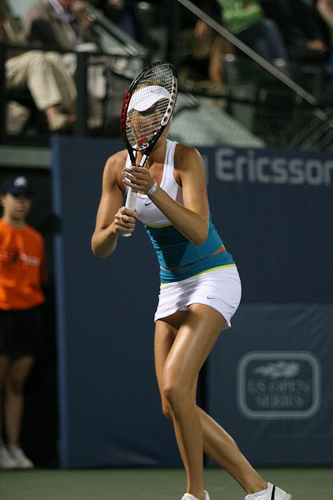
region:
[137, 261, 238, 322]
woman's skirt is white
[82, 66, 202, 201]
woman holding tennis racket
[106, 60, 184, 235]
racket is red and black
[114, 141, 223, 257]
shirt is blue and white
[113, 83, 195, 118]
woman wearing a visor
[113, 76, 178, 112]
the visor is white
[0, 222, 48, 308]
person's shirt is red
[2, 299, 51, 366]
person's shorts are black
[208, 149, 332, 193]
white letters on wall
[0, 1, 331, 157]
people sitting in stands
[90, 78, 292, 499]
woman is playing tennis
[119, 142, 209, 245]
woman's tan left arm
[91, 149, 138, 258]
woman's tan right arm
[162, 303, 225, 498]
woman's tan left leg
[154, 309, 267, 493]
woman's tan right leg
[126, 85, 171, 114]
woman wearing white visor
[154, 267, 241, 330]
woman wearing white Nike skirt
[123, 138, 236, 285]
woman wearing Nike tank top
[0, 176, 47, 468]
person in orange shirt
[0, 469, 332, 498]
tennis court is green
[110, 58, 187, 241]
modern tennis racquet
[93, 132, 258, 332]
women's tennis outfit by nike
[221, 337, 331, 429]
logo for the u.s. open tennis meet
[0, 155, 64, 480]
ball girl for tennis meet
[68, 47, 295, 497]
female tennis player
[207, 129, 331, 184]
logo for ericsson company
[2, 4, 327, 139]
crowd watching tennis meet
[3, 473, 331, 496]
hardcourt type of tennis court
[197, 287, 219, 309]
nike logo on womens' tennis shorts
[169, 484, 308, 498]
tennis shoes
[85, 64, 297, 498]
woman playing tennis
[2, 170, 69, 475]
person standing at the back of the court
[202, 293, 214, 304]
small symbol on the bottom of the skirt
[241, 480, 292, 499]
white and black tennis shoe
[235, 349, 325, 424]
white logo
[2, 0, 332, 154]
spectators sitting in the stands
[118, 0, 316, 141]
black railing along the incline of the stands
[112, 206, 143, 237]
fingers wrapped around the base of the racket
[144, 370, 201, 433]
knees are bent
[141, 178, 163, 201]
band around the wrist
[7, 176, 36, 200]
person wearing dark cap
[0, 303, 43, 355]
person wearing dark shorts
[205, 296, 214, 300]
Nike logo on skirt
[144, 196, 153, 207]
Nike logo on shirt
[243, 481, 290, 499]
right foot is back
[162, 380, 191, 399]
left knee is bent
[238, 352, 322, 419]
sign is US Open Series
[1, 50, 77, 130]
person in khaki slacks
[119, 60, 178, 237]
tennis racquet is red, black, and white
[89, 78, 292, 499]
woman is concentrating